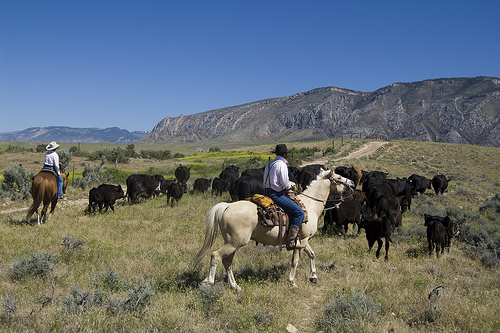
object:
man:
[260, 143, 308, 253]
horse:
[190, 167, 357, 295]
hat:
[270, 143, 291, 154]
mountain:
[138, 74, 496, 147]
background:
[0, 0, 500, 143]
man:
[28, 141, 67, 201]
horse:
[25, 171, 71, 226]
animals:
[423, 212, 455, 260]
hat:
[45, 140, 60, 150]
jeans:
[262, 188, 306, 228]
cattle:
[86, 183, 125, 217]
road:
[0, 140, 388, 217]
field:
[0, 140, 500, 329]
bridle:
[331, 176, 356, 195]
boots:
[284, 224, 308, 252]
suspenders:
[261, 156, 276, 191]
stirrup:
[285, 241, 302, 251]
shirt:
[261, 155, 295, 193]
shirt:
[43, 150, 62, 170]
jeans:
[39, 166, 65, 199]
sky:
[0, 0, 500, 134]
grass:
[0, 140, 500, 303]